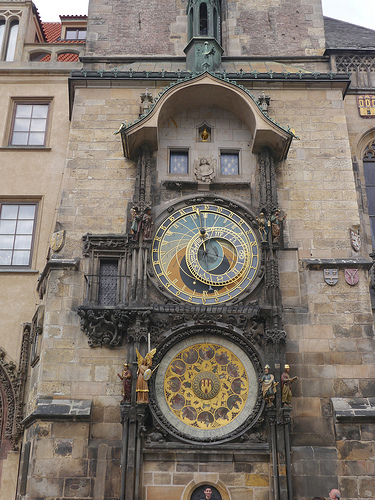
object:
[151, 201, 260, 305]
clock face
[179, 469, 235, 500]
arch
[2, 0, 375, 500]
building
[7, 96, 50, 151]
window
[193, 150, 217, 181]
statue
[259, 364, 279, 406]
statue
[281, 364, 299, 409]
statue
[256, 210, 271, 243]
statue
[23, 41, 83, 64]
balcony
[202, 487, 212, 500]
man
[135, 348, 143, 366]
wings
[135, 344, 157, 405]
statue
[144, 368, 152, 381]
shield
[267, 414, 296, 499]
column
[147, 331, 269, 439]
circle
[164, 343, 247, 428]
artwork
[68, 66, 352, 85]
ledge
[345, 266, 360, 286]
shields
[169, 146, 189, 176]
windows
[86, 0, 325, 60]
brick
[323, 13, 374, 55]
roof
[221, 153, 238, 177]
window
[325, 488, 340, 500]
man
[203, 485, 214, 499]
head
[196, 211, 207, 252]
hands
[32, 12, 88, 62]
roof